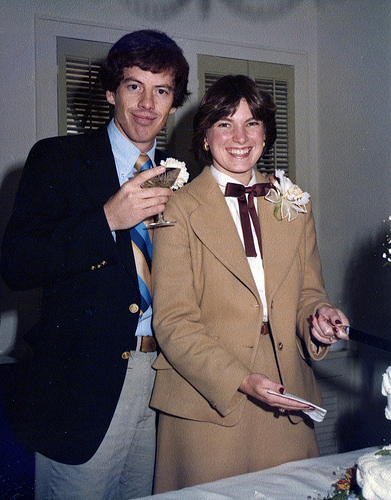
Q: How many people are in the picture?
A: Two.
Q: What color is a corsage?
A: White.